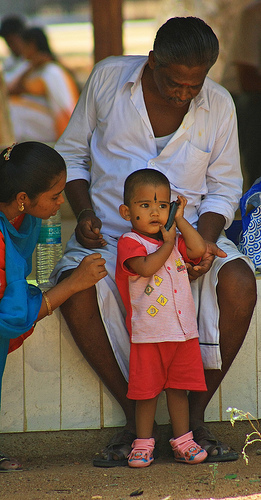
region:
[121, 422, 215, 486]
THE BABY IS WEARING TINY SHOES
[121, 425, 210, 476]
THE SHOES ARE PINK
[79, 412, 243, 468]
THE SANDALS ARE BLACK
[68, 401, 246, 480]
THE MAN IS WEARING SANDALS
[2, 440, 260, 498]
THE GROUND IS DIRT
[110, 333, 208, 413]
THE BABY IS WEARING SHORTS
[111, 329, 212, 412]
THE BABY'S SHORTS ARE RED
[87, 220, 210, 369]
THE BABY IS WEARING A PINK SHIRT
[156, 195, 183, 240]
THE BABY IS ON THE PHONE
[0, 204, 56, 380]
THE WOMAN IS WEARING BLUE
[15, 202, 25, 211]
gold earring in her ear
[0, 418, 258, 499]
brown dirt on the ground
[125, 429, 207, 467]
pink and blue shoes on her feet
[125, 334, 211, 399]
boy wearing red shorts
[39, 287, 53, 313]
gold bracelet on her arm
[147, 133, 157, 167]
clear buttons on the white shirt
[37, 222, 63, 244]
blue label on the clear bottle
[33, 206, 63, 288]
clear water bottle near the girl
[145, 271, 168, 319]
yellow diamonds on the boy's shirt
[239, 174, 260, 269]
blue and white bag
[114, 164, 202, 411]
The child is young.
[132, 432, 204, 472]
She is wearing pink shoes.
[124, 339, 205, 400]
She is wearing red pants.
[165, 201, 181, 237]
The phone is black.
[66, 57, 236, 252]
The man is wearing a white shirt.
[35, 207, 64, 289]
The water bottle is on the ledge.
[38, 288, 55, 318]
a gold bracelet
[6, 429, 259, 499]
The ground is dirt.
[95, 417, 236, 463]
The man has black sandels on.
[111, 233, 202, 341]
She is wearing a red shirt.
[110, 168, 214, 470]
A little kid standing up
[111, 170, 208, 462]
the kid is on the phone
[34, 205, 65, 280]
a water bottle beside the person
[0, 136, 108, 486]
a lady looking at the kid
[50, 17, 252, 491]
The person has on a white shirt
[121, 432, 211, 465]
pink shoes being worn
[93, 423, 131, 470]
A brown sandal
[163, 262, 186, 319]
red buttons on the shirt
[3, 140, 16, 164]
a colorful hair tie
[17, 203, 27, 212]
a gold earring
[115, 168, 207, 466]
the small child on the phone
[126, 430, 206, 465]
the shoes on the small child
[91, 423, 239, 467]
the sandals on the man's feet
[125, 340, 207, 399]
the shorts on the child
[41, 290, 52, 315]
the bracelet on the woman's arm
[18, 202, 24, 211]
the earring in the woman's ear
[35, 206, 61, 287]
the plastic water bottle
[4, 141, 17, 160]
the pin in the woman's hair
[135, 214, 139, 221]
the marking on the child's cheek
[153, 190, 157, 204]
the marking on the child's forehead